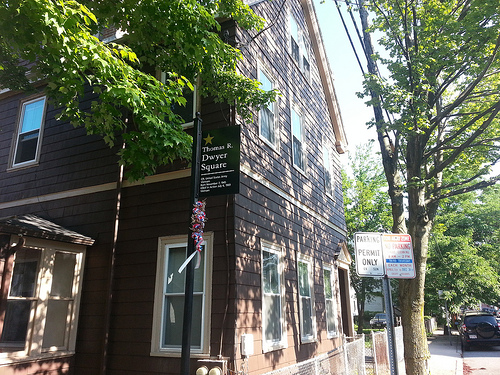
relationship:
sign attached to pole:
[198, 123, 246, 196] [180, 106, 203, 374]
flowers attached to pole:
[188, 197, 214, 257] [180, 106, 203, 374]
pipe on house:
[93, 4, 141, 375] [3, 2, 347, 367]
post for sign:
[382, 278, 400, 374] [354, 229, 390, 278]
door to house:
[336, 274, 361, 350] [3, 2, 347, 367]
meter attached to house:
[193, 358, 229, 374] [3, 2, 347, 367]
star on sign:
[202, 132, 218, 146] [198, 123, 246, 196]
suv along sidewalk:
[458, 307, 497, 352] [398, 327, 463, 374]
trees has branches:
[347, 2, 492, 375] [414, 6, 499, 123]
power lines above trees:
[336, 1, 452, 252] [347, 2, 491, 328]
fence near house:
[246, 326, 408, 374] [3, 2, 347, 367]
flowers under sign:
[188, 197, 214, 257] [198, 123, 246, 196]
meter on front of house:
[193, 358, 229, 374] [3, 2, 347, 367]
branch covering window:
[2, 0, 244, 170] [152, 46, 200, 147]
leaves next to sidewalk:
[462, 359, 482, 374] [398, 327, 463, 374]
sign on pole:
[198, 123, 246, 196] [180, 106, 203, 374]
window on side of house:
[9, 89, 57, 173] [3, 2, 347, 367]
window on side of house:
[152, 46, 200, 147] [3, 2, 347, 367]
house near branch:
[3, 2, 347, 367] [2, 0, 244, 170]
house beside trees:
[3, 2, 347, 367] [347, 2, 492, 375]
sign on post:
[354, 229, 390, 278] [382, 278, 400, 374]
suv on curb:
[458, 307, 497, 352] [454, 335, 464, 374]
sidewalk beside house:
[398, 327, 463, 374] [3, 2, 347, 367]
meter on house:
[193, 358, 229, 374] [3, 2, 347, 367]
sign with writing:
[198, 123, 246, 196] [200, 143, 236, 187]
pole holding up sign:
[180, 106, 203, 374] [198, 123, 246, 196]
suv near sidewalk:
[458, 307, 497, 352] [398, 327, 463, 374]